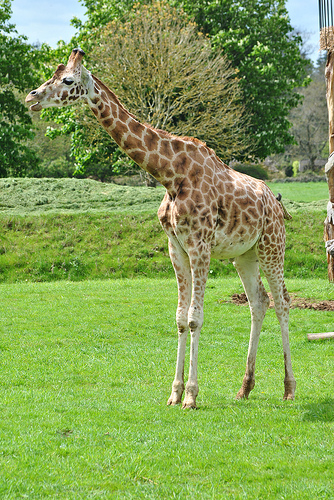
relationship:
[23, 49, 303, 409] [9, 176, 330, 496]
giraffe standing on grass